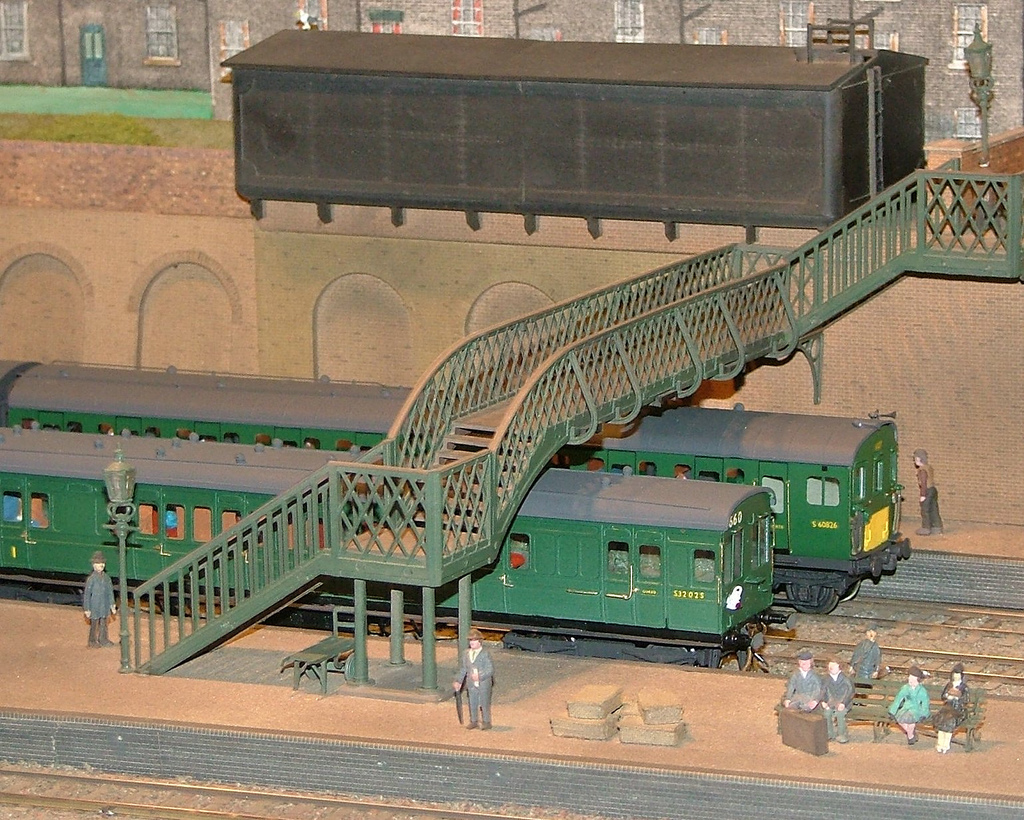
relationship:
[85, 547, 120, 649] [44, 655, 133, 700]
man standing on platform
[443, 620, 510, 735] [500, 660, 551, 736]
man standing on platform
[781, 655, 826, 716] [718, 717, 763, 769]
man standing on platform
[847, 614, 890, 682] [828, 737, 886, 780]
man standing on platform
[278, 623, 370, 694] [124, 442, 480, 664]
bench under stairs